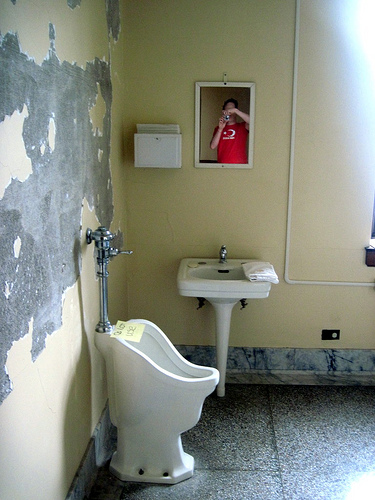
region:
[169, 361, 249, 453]
The urinal is white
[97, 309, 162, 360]
The urinal has a sign on it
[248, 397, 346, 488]
The floor is dark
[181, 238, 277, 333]
The sink is empty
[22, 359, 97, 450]
The wall is light colored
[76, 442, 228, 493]
The urinal is connected to the floor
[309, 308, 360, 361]
The outlet is covered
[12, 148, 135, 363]
The floor has gray patches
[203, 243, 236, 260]
The faucet is metal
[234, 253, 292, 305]
The towel is white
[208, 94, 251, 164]
man's reflection in a mirror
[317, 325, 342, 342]
black cover on an electrical outlet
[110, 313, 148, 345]
out of order sign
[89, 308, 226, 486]
place for humans to use restroom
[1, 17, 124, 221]
wall with peeled paint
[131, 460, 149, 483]
bolt holding toilet to floor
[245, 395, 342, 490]
speckled tiled floor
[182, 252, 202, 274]
bar of soap on a sink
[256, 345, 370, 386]
faux marble, wide baseboard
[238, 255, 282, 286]
folded towel resting on a bathroom sink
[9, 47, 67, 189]
Paint chipped on the wall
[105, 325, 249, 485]
White urinal on the floor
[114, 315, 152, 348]
Yellow sign on urinal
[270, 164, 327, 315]
Water pipe on the wall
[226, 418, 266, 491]
Crack in the floor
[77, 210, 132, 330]
Silver handle on toilet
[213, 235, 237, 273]
Silver faucet on the sink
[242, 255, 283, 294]
Towel on side of sink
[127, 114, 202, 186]
Paper towel holder on the wall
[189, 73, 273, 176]
Mirror on the wall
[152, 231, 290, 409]
pedestal sink against wall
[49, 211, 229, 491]
white urinal against wall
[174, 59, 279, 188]
man taking picture in mirror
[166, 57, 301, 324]
mirror mounted above pedestal sink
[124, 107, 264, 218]
paper towel dispenser next to mirror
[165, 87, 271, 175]
man in mirror wearing a red t-shirt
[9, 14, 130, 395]
paint peeling off wall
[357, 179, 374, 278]
edge of window sill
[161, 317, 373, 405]
marble baseboard with trim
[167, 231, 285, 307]
bar of soap on sink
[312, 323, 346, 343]
electric outlet at bottom of wall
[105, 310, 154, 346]
yellow sign on urinal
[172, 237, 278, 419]
smal white sink against wall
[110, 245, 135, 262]
silver flusher attached to urinal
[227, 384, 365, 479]
tiles bathroom floor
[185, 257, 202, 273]
bar of soap resting on bathroom surface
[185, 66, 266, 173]
white framed mirror on the walll?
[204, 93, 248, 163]
photographer's reflection in bathroom mirror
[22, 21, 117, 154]
grey mottled section of wall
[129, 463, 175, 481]
two bolts on side white urinal